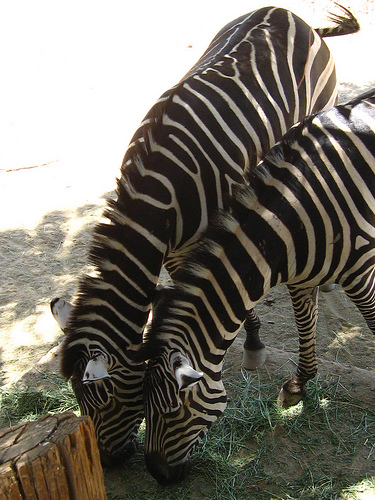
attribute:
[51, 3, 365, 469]
zebra — grazing, eating, striped, black, white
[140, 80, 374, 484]
zebra — grazing, eating, striped, black, white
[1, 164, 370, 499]
ground — dirt, brown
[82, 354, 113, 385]
ear — black, white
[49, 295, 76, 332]
ear — black, white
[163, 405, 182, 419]
eye — black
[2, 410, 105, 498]
wood — trunk, stump, brown, post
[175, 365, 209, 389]
ear — white, black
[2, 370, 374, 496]
hay — present, green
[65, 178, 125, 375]
mane — black, white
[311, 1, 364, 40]
tail — black, white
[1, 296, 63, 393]
sunlight — bright